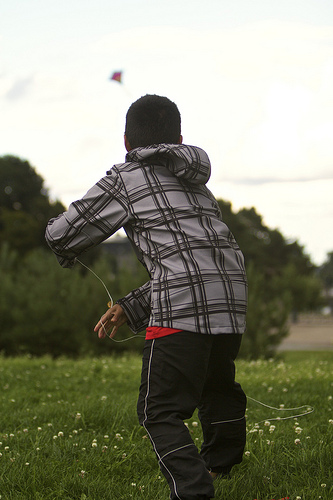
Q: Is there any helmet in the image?
A: No, there are no helmets.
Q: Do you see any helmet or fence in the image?
A: No, there are no helmets or fences.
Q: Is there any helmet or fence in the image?
A: No, there are no helmets or fences.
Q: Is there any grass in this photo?
A: Yes, there is grass.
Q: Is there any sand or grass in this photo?
A: Yes, there is grass.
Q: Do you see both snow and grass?
A: No, there is grass but no snow.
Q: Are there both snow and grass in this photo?
A: No, there is grass but no snow.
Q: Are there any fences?
A: No, there are no fences.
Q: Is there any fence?
A: No, there are no fences.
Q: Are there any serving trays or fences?
A: No, there are no fences or serving trays.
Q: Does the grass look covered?
A: Yes, the grass is covered.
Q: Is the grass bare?
A: No, the grass is covered.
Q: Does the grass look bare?
A: No, the grass is covered.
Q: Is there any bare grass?
A: No, there is grass but it is covered.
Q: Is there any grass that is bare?
A: No, there is grass but it is covered.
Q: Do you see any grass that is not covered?
A: No, there is grass but it is covered.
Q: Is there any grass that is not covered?
A: No, there is grass but it is covered.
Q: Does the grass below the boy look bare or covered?
A: The grass is covered.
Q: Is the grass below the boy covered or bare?
A: The grass is covered.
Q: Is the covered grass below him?
A: Yes, the grass is below the boy.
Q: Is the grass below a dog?
A: No, the grass is below the boy.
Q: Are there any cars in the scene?
A: No, there are no cars.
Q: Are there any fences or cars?
A: No, there are no cars or fences.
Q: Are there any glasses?
A: No, there are no glasses.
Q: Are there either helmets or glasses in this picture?
A: No, there are no glasses or helmets.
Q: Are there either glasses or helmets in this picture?
A: No, there are no glasses or helmets.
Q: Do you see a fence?
A: No, there are no fences.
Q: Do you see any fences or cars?
A: No, there are no fences or cars.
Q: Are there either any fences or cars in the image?
A: No, there are no fences or cars.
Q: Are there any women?
A: No, there are no women.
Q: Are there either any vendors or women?
A: No, there are no women or vendors.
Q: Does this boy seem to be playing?
A: Yes, the boy is playing.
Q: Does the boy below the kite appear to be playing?
A: Yes, the boy is playing.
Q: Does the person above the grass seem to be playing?
A: Yes, the boy is playing.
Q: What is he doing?
A: The boy is playing.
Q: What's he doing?
A: The boy is playing.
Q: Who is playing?
A: The boy is playing.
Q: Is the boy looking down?
A: No, the boy is playing.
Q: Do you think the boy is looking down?
A: No, the boy is playing.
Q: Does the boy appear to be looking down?
A: No, the boy is playing.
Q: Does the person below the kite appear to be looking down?
A: No, the boy is playing.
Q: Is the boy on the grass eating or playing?
A: The boy is playing.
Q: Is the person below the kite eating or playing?
A: The boy is playing.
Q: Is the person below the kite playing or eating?
A: The boy is playing.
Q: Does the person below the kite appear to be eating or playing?
A: The boy is playing.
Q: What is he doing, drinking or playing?
A: The boy is playing.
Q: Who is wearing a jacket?
A: The boy is wearing a jacket.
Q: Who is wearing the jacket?
A: The boy is wearing a jacket.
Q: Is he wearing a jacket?
A: Yes, the boy is wearing a jacket.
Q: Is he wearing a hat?
A: No, the boy is wearing a jacket.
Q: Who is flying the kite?
A: The boy is flying the kite.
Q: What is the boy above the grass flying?
A: The boy is flying the kite.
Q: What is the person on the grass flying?
A: The boy is flying the kite.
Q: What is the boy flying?
A: The boy is flying the kite.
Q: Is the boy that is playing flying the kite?
A: Yes, the boy is flying the kite.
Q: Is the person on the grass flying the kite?
A: Yes, the boy is flying the kite.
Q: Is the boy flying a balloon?
A: No, the boy is flying the kite.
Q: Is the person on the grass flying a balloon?
A: No, the boy is flying the kite.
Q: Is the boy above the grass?
A: Yes, the boy is above the grass.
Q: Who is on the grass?
A: The boy is on the grass.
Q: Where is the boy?
A: The boy is on the grass.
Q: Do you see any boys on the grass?
A: Yes, there is a boy on the grass.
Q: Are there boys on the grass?
A: Yes, there is a boy on the grass.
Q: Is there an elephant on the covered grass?
A: No, there is a boy on the grass.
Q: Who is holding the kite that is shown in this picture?
A: The boy is holding the kite.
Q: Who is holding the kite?
A: The boy is holding the kite.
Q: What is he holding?
A: The boy is holding the kite.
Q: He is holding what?
A: The boy is holding the kite.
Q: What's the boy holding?
A: The boy is holding the kite.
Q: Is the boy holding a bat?
A: No, the boy is holding the kite.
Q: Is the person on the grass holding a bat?
A: No, the boy is holding the kite.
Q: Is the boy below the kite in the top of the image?
A: Yes, the boy is below the kite.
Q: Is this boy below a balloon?
A: No, the boy is below the kite.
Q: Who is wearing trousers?
A: The boy is wearing trousers.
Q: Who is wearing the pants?
A: The boy is wearing trousers.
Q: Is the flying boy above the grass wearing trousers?
A: Yes, the boy is wearing trousers.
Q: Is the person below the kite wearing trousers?
A: Yes, the boy is wearing trousers.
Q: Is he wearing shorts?
A: No, the boy is wearing trousers.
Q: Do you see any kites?
A: Yes, there is a kite.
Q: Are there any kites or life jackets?
A: Yes, there is a kite.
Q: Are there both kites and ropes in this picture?
A: No, there is a kite but no ropes.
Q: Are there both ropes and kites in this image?
A: No, there is a kite but no ropes.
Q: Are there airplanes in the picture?
A: No, there are no airplanes.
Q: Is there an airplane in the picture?
A: No, there are no airplanes.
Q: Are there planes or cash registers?
A: No, there are no planes or cash registers.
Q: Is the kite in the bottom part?
A: No, the kite is in the top of the image.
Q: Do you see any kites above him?
A: Yes, there is a kite above the boy.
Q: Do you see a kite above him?
A: Yes, there is a kite above the boy.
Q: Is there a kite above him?
A: Yes, there is a kite above the boy.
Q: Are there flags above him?
A: No, there is a kite above the boy.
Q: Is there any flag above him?
A: No, there is a kite above the boy.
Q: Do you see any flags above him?
A: No, there is a kite above the boy.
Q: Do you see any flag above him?
A: No, there is a kite above the boy.